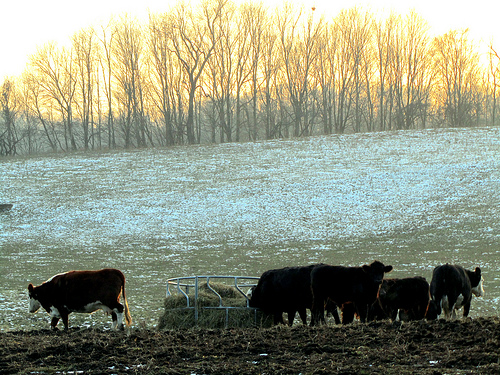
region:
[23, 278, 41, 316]
the head of a cow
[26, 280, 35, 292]
the ear of a cow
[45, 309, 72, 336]
the front legs of a cow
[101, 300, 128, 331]
the hind legs of a cow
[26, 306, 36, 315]
the nose of a cow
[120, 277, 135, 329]
the tail of a cow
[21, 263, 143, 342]
a brown and white cow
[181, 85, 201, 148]
the trunk of a tree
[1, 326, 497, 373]
a dirt field under the cows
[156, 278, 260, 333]
hay in a pen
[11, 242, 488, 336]
group of cows standing together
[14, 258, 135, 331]
brown and white cow on left side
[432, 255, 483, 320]
black and white cow on right side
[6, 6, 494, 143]
leafless trees in the background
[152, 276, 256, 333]
bales of hay for cows to eat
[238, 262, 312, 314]
cow eating from hay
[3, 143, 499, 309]
hill behind group of cows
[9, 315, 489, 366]
dirt area cows are standing on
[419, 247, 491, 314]
cow walking away from group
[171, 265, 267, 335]
metal bars around hay bales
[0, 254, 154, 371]
this is a cow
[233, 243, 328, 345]
this is a cow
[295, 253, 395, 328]
this is a cow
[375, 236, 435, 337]
this is a cow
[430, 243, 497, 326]
this is a cow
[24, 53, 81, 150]
this is a tree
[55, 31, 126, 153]
this is a tree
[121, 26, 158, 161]
this is a tree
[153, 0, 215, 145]
this is a tree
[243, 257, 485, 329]
the cattle in the field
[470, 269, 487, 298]
the white face of the cow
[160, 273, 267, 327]
the bars of the pen full of hay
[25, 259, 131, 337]
the brown and white cow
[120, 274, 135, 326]
the tail of the cow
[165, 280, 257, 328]
the hey piled up inside the pen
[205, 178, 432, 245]
snow on the hillside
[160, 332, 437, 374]
dirt and grass sprouting out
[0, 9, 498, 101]
The sunlight going through the trees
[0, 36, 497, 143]
the bare trees in behind the field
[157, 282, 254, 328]
the hay for winter food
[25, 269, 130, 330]
a cow walking away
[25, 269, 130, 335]
a cow walking to the left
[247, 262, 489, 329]
a small herd of cattle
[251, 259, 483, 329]
a small group of cattle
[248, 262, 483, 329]
cattle gathered near their food supply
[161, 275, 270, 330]
container for the hay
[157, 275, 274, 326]
hay dispenser for the cattle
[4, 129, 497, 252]
remnants of snow on a hillside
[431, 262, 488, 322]
a white faced cow